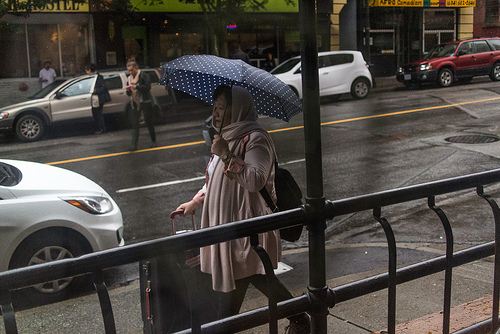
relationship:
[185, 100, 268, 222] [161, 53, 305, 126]
woman with umbrella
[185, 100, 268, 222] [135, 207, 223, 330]
woman with luggage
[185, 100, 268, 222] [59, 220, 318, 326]
woman at sidewalk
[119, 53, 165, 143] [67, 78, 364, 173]
girl in street